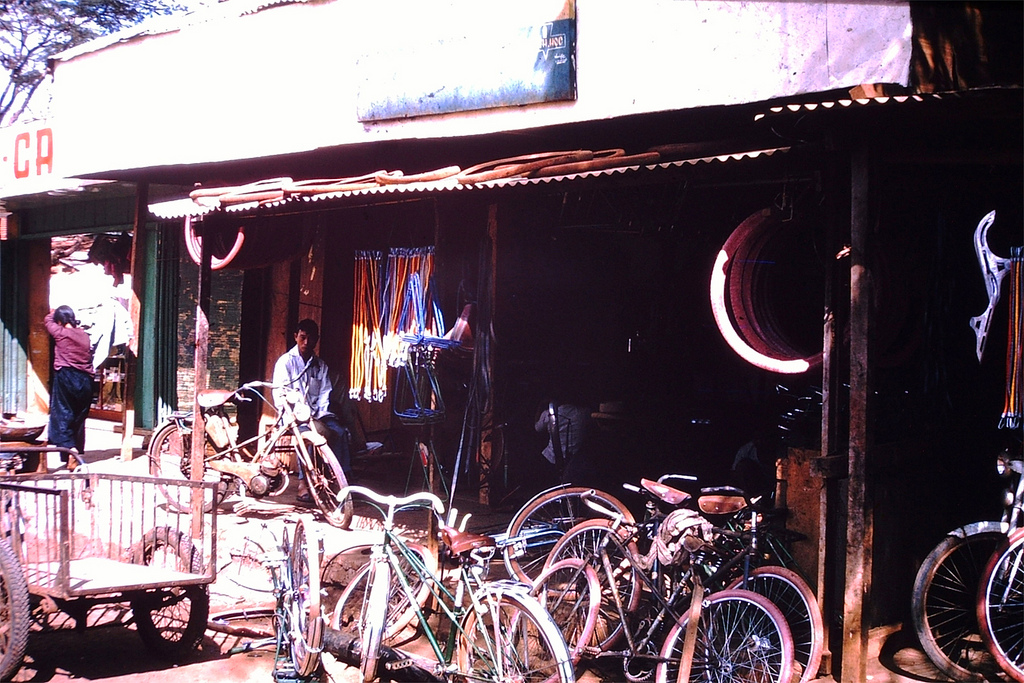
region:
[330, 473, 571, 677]
bicycle outside bike shop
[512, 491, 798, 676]
bicycle outside bike shop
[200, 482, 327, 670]
bicycle outside bike shop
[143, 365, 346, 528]
bicycle outside bike shop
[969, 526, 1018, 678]
bicycle outside bike shop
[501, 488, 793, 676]
bicycle outside bike shop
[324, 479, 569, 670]
bicycle outside bike shop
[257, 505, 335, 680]
bicycle outside bike shop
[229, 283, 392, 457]
man next to the bike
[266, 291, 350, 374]
head of the man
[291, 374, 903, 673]
many bikes on the ground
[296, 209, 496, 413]
items next to man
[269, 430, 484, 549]
handlebars on the bike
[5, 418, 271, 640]
back of the vehicle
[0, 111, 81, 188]
letters on the building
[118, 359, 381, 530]
bike next to man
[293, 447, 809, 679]
A set of bicycles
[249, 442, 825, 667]
The set of bicycles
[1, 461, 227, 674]
The metal cart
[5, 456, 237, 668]
A metal cart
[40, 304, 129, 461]
A woman wearing a long shirt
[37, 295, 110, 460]
The long shirt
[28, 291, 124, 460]
The short haired woman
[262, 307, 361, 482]
A man sitting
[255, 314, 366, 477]
The seated man in a white shirt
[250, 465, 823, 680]
Bicycles parked on the sidewalk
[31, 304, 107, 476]
Woman in purple shirt leaning against post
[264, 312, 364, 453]
Man in white shirt sitting on porch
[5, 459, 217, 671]
Wagon with open back parked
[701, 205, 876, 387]
Bicycle tires hanging from hook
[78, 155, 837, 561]
Porch in front of buiding with awning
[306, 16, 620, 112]
faded sign on store front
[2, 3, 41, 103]
tall tree with many leaf buds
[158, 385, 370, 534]
Woman's bicycle with brown seat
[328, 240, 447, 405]
Colored curtain hanging infront of window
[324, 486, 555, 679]
a bike on the sidewalk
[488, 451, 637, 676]
a bike on the sidewalk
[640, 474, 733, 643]
a bike on the sidewalk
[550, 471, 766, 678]
a bike on the sidewalk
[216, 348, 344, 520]
a bike on the sidewalk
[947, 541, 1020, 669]
a bike on the sidewalk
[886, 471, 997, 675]
a bike on the sidewalk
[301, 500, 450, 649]
a bike on the sidewalk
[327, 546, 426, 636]
a bike on the sidewalk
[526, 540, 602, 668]
a bike on the sidewalk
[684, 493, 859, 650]
a bike on the sidewalk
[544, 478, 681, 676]
a bike on the sidewalk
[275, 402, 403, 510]
a bike on the sidewalk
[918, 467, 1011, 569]
a bike on the sidewalk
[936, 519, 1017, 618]
a bike on the sidewalk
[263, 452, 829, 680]
a bunch of bikes parked on a sidewalk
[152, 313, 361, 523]
a man beside his bike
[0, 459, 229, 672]
small metal cart with wheels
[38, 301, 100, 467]
person in a red shirt